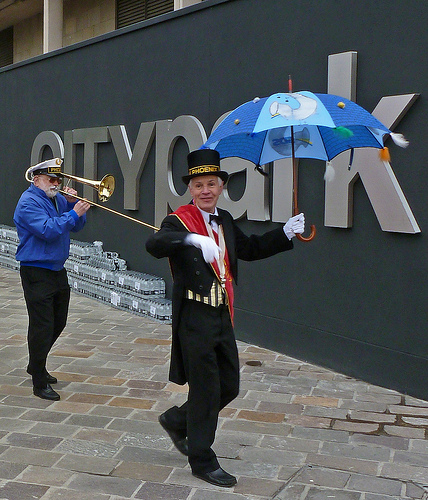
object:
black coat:
[144, 198, 295, 386]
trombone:
[51, 169, 160, 244]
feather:
[377, 146, 391, 161]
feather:
[390, 132, 411, 150]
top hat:
[179, 149, 230, 188]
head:
[187, 177, 223, 210]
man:
[144, 147, 305, 489]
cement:
[69, 328, 196, 474]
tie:
[209, 214, 223, 225]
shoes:
[191, 465, 237, 488]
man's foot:
[32, 382, 60, 400]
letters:
[106, 120, 156, 212]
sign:
[1, 0, 428, 404]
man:
[13, 157, 91, 401]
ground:
[0, 264, 428, 500]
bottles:
[160, 278, 166, 299]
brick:
[303, 405, 350, 422]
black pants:
[20, 266, 71, 390]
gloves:
[184, 234, 223, 263]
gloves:
[282, 212, 305, 241]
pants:
[163, 305, 240, 477]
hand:
[189, 233, 220, 264]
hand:
[282, 212, 305, 241]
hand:
[63, 186, 78, 203]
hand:
[73, 196, 91, 217]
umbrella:
[200, 73, 411, 244]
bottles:
[144, 279, 150, 300]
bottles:
[159, 303, 166, 326]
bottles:
[113, 259, 119, 271]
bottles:
[15, 232, 18, 243]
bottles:
[98, 286, 102, 303]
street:
[8, 386, 149, 489]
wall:
[2, 0, 428, 402]